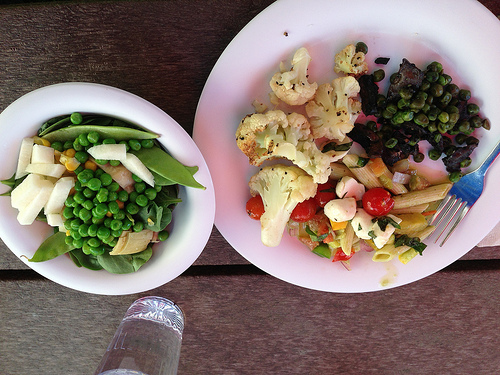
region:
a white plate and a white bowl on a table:
[13, 8, 484, 301]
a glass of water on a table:
[95, 305, 195, 371]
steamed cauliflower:
[250, 50, 332, 190]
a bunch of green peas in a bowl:
[57, 178, 115, 244]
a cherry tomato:
[363, 187, 395, 217]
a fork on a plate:
[439, 141, 493, 252]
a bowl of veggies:
[17, 110, 201, 282]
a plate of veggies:
[241, 35, 487, 238]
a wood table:
[233, 291, 492, 350]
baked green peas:
[393, 69, 480, 144]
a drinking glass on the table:
[85, 290, 188, 373]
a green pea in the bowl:
[82, 175, 104, 191]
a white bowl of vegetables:
[2, 79, 219, 299]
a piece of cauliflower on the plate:
[242, 160, 323, 252]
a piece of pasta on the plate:
[391, 180, 456, 212]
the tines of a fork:
[417, 167, 487, 251]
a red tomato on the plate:
[360, 186, 402, 217]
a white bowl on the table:
[0, 76, 218, 300]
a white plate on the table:
[186, 1, 499, 297]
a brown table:
[1, 0, 499, 373]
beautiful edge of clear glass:
[119, 296, 206, 334]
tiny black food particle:
[275, 27, 295, 39]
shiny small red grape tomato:
[356, 179, 395, 223]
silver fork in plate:
[438, 187, 470, 250]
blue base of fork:
[441, 169, 498, 202]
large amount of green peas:
[71, 200, 116, 228]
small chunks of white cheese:
[13, 165, 78, 205]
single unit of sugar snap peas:
[120, 135, 204, 206]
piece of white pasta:
[382, 182, 458, 226]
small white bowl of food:
[10, 75, 217, 305]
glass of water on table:
[83, 296, 208, 372]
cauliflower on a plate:
[230, 100, 332, 180]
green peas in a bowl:
[65, 190, 110, 237]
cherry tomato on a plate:
[360, 185, 390, 215]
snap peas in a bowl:
[150, 155, 205, 190]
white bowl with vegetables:
[0, 66, 225, 301]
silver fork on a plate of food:
[420, 125, 495, 270]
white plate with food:
[194, 0, 499, 318]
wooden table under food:
[248, 300, 498, 374]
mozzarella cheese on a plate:
[324, 194, 356, 228]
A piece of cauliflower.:
[242, 160, 314, 258]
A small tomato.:
[356, 182, 401, 227]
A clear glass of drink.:
[93, 298, 186, 373]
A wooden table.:
[237, 303, 411, 373]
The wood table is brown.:
[249, 301, 452, 373]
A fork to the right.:
[417, 124, 497, 254]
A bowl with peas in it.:
[9, 122, 191, 264]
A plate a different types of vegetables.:
[204, 17, 496, 257]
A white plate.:
[200, 11, 492, 286]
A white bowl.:
[0, 77, 223, 307]